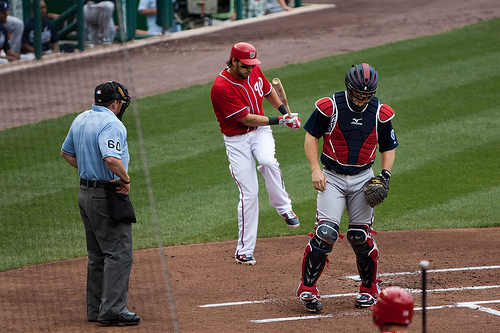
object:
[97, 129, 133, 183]
arm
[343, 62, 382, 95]
helmet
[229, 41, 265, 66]
helmet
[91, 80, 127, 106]
helmet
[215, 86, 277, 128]
arm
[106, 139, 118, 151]
number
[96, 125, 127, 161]
sleeve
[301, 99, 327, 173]
arm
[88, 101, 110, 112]
collar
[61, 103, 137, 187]
shirt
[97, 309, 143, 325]
shoe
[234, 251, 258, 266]
shoe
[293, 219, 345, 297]
leg pad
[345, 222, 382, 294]
leg pad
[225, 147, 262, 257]
legs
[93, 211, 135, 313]
legs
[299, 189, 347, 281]
legs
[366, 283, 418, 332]
person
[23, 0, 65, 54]
person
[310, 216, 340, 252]
kneepads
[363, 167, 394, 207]
glove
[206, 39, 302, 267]
player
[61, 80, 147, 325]
umpire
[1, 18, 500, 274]
grass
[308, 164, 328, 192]
hand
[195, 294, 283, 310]
lines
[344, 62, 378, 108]
head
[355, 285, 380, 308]
sneakers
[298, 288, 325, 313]
sneakers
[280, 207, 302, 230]
sneakers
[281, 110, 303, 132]
hand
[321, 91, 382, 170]
vest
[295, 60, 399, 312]
catcher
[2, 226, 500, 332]
dirt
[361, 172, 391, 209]
hand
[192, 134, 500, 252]
pattern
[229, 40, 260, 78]
head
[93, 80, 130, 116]
head